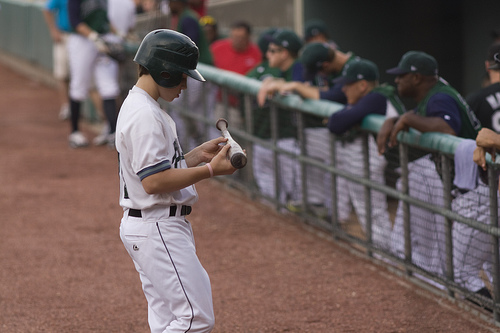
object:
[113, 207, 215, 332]
pants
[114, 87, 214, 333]
uniform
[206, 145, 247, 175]
hand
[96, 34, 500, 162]
barrier top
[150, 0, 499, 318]
dugout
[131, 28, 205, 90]
helmet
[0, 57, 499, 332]
ground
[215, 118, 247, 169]
baseball bat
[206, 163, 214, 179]
band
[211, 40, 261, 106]
shirt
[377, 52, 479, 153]
men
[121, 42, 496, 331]
barrier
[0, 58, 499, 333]
dirt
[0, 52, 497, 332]
field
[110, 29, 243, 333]
boy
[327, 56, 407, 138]
teammates